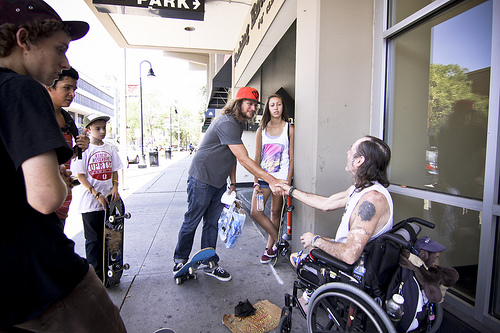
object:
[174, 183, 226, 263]
jeans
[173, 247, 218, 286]
skateboard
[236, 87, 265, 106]
cap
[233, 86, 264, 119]
head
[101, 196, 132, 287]
skateboard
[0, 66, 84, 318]
t-shirt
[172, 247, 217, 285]
blue skateboard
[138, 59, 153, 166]
street light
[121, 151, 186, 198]
curb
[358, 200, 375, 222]
tattoo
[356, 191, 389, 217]
shoulder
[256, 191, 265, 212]
bottle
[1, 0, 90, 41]
hat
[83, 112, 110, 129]
hat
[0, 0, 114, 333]
teenagers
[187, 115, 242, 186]
shirt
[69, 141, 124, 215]
shirt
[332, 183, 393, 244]
shirt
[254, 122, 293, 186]
shirt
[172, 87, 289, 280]
man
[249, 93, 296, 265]
girl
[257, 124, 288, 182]
top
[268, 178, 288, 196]
hands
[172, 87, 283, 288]
boy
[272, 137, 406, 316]
man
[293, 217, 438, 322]
wheel chair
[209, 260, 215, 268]
wheels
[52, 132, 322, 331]
ground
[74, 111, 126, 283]
boy